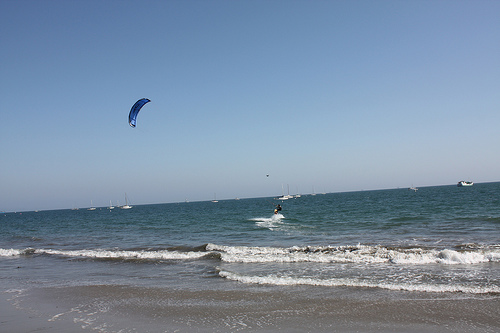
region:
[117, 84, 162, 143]
blue parasailing sail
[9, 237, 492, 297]
waves breaking on the shore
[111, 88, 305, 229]
person parasailing in the ocean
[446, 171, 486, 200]
boat in the distance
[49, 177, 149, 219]
group of boats in the water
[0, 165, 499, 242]
the water is calm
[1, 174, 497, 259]
blue ocean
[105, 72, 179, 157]
parasailing sail in the air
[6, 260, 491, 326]
wet sandy beach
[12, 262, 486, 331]
water on the sand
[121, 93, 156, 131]
a blue kite in the sky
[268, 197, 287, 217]
a man on the water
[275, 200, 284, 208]
the head of a man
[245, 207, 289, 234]
white water behind the man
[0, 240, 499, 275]
a small white wave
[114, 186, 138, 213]
a white boat on the water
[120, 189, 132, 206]
the mast of a boat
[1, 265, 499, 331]
brown sand on the beach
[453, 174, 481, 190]
a boat without a mast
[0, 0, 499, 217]
a clear blue sky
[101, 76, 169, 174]
water kite in sky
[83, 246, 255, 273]
wave on the water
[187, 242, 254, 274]
breaking wave on water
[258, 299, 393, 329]
wet sand on beach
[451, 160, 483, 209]
boat on the horizon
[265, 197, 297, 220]
person in the water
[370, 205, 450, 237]
ripples on the water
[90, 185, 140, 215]
boats in the distance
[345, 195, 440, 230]
top of the ocean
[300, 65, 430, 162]
blue sky above person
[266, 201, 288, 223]
person in the water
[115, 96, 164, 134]
kite in the sky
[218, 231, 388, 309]
the ocean water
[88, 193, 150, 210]
boats in the water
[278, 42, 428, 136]
the sky is bright blue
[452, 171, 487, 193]
boat in the water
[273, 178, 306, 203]
white boats in the water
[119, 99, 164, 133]
kite is blue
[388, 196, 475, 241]
the water is blue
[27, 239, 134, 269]
water is white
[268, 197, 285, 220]
a person on the water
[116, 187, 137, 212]
a boat on the water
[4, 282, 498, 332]
a brown sandy beach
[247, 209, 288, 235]
white water behind the person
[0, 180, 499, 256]
blue ocean water